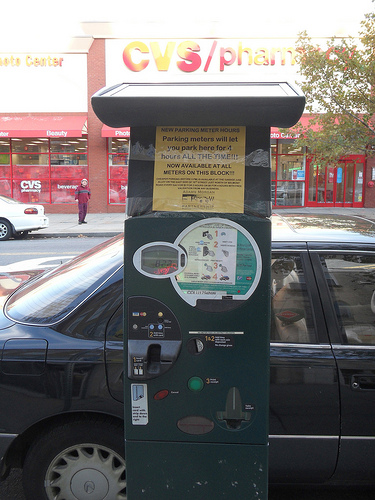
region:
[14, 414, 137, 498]
The back wheel of the car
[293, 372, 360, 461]
The car is the color black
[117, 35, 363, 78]
The sign on the front of the store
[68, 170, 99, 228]
The man standing on the sidewalk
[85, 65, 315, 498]
The parking meter on the sidewalk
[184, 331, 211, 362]
The coin slot for the meter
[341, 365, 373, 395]
The handle to the car door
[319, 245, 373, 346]
The window to the car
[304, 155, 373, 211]
The door to the store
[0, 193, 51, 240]
The white car parked on the street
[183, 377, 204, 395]
The green button on the machine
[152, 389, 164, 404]
The red button on the machine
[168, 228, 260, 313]
The instructions on the machine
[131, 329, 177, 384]
The money slot on the machine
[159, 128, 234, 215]
The yellow sign on the machine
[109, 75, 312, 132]
The solar panel on top of the machine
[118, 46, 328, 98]
The cvs pharmacy sign behind the machine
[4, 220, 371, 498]
The black car behind the machine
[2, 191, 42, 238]
The white car behind the machine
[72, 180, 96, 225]
The person on the sidewalk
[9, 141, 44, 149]
window of a building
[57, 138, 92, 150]
window of a building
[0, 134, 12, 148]
window of a building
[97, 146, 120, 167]
window of a building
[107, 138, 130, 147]
window of a building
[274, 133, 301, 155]
window of a building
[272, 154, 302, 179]
window of a building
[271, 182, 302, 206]
window of a building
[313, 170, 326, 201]
window of a building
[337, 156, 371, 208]
window of a building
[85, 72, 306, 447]
a parking meter with ridiculously complicated instructions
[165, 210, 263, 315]
numbered step by step instructions to use the confusing meter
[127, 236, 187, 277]
a number displayed in this window means something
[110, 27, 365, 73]
a CVS pharmacy is across the street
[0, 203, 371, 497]
a car is parked at the confusing meter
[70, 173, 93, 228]
a pedestrian looks on from across the street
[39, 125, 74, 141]
the CVS pharmacy sells beauty products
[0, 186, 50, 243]
a white sedan is parked across the street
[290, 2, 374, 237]
a shade tree planted at the curb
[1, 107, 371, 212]
the CVS pharmacy is mainly red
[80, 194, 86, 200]
the shirt is red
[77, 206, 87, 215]
the pants are purple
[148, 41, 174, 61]
sun is reflecting on the sign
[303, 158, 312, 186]
the frame is red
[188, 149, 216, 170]
the sign is yellow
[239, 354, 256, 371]
the box is green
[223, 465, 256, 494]
the paint is chipping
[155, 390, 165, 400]
the button is red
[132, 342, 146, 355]
the credit card dispencer is gray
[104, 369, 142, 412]
the car is by the box